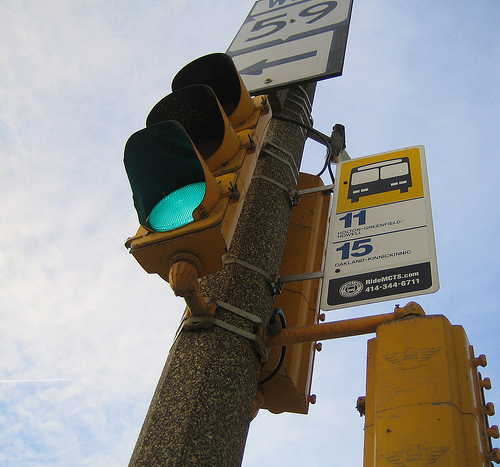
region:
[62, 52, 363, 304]
a green traffic light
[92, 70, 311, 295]
a green traffic light on a pole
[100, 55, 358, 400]
a green traffic light on a metal pole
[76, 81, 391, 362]
a green traffic light with yellow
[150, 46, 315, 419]
a pole with a traffic light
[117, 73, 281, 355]
a metal pole with traffic light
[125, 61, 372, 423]
a light on a pole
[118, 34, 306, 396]
a light on a metal pole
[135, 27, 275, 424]
a pole with a light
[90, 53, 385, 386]
a metal pole with a light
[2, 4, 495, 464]
cloud cover in sky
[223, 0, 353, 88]
black and white sign on pole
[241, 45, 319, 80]
black arrow on white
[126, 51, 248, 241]
three covers over lights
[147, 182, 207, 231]
glowing green traffic light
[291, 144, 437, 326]
vertical sign on two bars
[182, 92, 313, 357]
metal brackets around pole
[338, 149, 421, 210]
bus icon on sign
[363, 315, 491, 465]
yellow back of traffic light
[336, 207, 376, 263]
blue numbers on white sign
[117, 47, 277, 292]
this traffic light is currently green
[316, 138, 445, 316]
a sign about the bus lines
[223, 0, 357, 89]
another sign on the street light pole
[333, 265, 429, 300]
phone number for bus line information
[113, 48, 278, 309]
the street light is painted yellow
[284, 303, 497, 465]
street equipment is painted yellow to stand out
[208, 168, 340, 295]
metal straps hold the bus sign in place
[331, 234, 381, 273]
bus line 15 connects to Oakland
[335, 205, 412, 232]
bus line 11 connects to Greenfield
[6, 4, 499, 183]
the sky has scattered clouds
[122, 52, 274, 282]
an illuminated green light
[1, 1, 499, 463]
a cloudy blue sky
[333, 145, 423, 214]
a yellow sign with an images of a bus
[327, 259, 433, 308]
a black sign with a phone number written in white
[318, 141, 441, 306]
a white sign with the numbers 11 and 15 in blue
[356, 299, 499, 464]
the yellow back of a traffic control light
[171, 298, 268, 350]
metal bands around a pole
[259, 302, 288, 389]
black electrical cord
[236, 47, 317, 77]
a black arrow pointing left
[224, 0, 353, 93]
a white and black sign with the number 59 on it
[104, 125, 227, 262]
the light is green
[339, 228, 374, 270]
the number is 15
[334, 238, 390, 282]
the number is 15